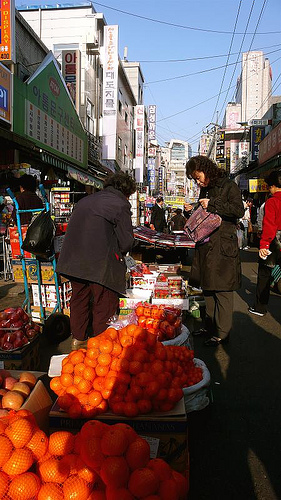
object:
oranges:
[127, 321, 138, 338]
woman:
[184, 155, 246, 351]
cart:
[4, 181, 75, 344]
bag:
[0, 409, 190, 499]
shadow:
[215, 308, 278, 498]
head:
[102, 170, 136, 195]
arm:
[112, 206, 135, 254]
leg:
[69, 269, 90, 355]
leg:
[90, 282, 118, 336]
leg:
[211, 288, 233, 343]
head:
[185, 154, 213, 187]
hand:
[199, 197, 210, 211]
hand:
[185, 203, 192, 214]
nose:
[195, 178, 200, 184]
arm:
[258, 199, 272, 248]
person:
[247, 169, 281, 317]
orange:
[76, 379, 92, 393]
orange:
[92, 373, 106, 388]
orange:
[60, 359, 75, 376]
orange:
[47, 375, 65, 390]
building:
[155, 133, 195, 203]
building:
[0, 0, 145, 262]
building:
[229, 102, 281, 226]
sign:
[11, 50, 89, 170]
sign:
[61, 48, 80, 118]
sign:
[100, 23, 117, 160]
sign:
[133, 104, 144, 183]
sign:
[237, 141, 249, 168]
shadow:
[107, 328, 188, 477]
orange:
[127, 359, 142, 374]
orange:
[154, 345, 167, 359]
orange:
[165, 385, 177, 401]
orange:
[122, 400, 137, 415]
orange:
[125, 435, 150, 469]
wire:
[88, 0, 280, 37]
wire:
[119, 41, 281, 64]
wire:
[209, 0, 265, 124]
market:
[1, 156, 281, 498]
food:
[1, 221, 202, 496]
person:
[149, 195, 167, 231]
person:
[169, 208, 186, 236]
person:
[183, 199, 195, 220]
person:
[242, 199, 253, 250]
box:
[7, 220, 68, 260]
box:
[29, 279, 73, 308]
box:
[30, 305, 70, 324]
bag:
[18, 208, 53, 259]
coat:
[54, 183, 136, 298]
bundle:
[1, 408, 190, 498]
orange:
[98, 427, 127, 456]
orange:
[127, 466, 159, 497]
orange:
[38, 459, 70, 484]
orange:
[3, 418, 35, 448]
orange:
[47, 430, 75, 455]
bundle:
[48, 323, 204, 418]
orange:
[119, 335, 133, 346]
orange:
[97, 352, 112, 364]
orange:
[134, 371, 149, 387]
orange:
[86, 388, 101, 406]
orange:
[86, 336, 100, 348]